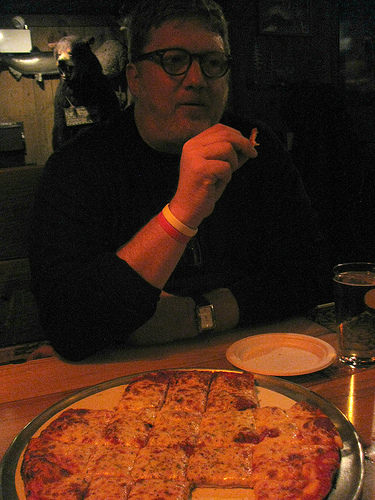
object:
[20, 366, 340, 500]
snacks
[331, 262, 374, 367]
cup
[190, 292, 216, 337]
watch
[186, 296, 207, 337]
wrist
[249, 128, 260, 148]
food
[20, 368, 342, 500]
pizza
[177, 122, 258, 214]
hand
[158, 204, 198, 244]
wrist band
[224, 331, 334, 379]
plate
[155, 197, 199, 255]
wrist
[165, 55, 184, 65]
eye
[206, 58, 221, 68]
eye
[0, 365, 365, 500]
platter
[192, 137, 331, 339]
arm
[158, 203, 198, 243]
fireplace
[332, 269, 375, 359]
liquid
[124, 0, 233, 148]
head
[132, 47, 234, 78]
glasses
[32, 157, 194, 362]
arm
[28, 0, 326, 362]
man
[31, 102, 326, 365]
shirt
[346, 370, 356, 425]
light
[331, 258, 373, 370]
glass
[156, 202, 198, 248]
bracelet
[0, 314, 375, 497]
table